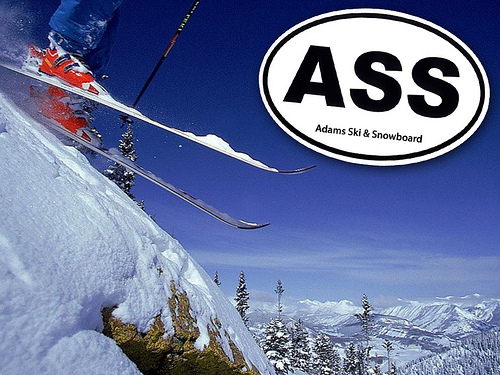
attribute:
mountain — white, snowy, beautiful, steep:
[4, 146, 221, 331]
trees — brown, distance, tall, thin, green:
[238, 282, 365, 375]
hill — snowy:
[97, 232, 225, 374]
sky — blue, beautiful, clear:
[190, 153, 474, 311]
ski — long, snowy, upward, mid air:
[114, 98, 317, 177]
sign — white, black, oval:
[268, 43, 495, 157]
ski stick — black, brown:
[116, 4, 187, 107]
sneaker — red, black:
[44, 41, 92, 89]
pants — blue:
[58, 5, 119, 64]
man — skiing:
[35, 5, 119, 147]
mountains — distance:
[262, 291, 486, 347]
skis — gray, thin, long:
[79, 116, 287, 228]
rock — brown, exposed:
[130, 286, 238, 375]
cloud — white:
[285, 241, 467, 297]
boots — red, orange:
[37, 50, 105, 113]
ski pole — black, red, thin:
[145, 29, 189, 74]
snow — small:
[201, 128, 260, 158]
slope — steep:
[19, 128, 210, 346]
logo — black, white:
[291, 38, 459, 147]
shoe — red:
[56, 109, 97, 135]